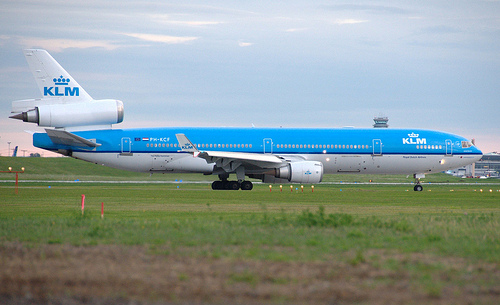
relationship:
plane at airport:
[9, 47, 486, 191] [473, 152, 500, 178]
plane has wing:
[9, 47, 486, 191] [178, 148, 307, 172]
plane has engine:
[9, 47, 486, 191] [266, 160, 325, 184]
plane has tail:
[9, 47, 486, 191] [25, 49, 115, 130]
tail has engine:
[25, 49, 115, 130] [9, 99, 125, 126]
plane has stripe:
[9, 47, 486, 191] [42, 149, 485, 158]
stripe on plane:
[42, 149, 485, 158] [9, 47, 486, 191]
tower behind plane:
[372, 117, 391, 128] [9, 47, 486, 191]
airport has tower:
[473, 152, 500, 178] [372, 117, 391, 128]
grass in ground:
[1, 158, 498, 303] [1, 157, 498, 302]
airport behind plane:
[473, 152, 500, 178] [9, 47, 486, 191]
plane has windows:
[9, 47, 486, 191] [144, 138, 482, 154]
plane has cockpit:
[9, 47, 486, 191] [461, 141, 471, 151]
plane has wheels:
[9, 47, 486, 191] [211, 181, 258, 192]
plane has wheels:
[9, 47, 486, 191] [411, 182, 426, 192]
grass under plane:
[1, 158, 498, 303] [9, 47, 486, 191]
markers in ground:
[78, 191, 107, 219] [1, 157, 498, 302]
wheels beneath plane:
[211, 181, 258, 192] [9, 47, 486, 191]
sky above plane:
[1, 2, 499, 156] [9, 47, 486, 191]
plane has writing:
[9, 47, 486, 191] [42, 86, 79, 95]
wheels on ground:
[211, 181, 258, 192] [2, 157, 498, 302]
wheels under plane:
[211, 181, 258, 192] [9, 47, 486, 191]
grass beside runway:
[1, 158, 498, 303] [1, 177, 496, 190]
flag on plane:
[141, 136, 151, 143] [9, 47, 486, 191]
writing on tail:
[42, 86, 79, 95] [25, 49, 115, 130]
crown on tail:
[52, 74, 72, 86] [25, 49, 115, 130]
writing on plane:
[42, 86, 79, 95] [9, 47, 486, 191]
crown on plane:
[52, 74, 72, 86] [9, 47, 486, 191]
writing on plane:
[401, 137, 428, 145] [9, 47, 486, 191]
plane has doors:
[9, 47, 486, 191] [118, 135, 456, 158]